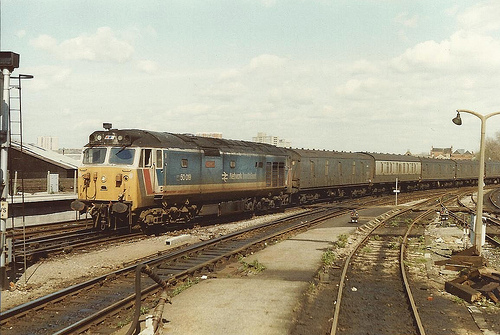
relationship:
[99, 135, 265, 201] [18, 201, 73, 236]
train on track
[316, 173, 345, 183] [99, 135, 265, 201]
dirt on train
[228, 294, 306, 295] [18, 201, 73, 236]
pavement between track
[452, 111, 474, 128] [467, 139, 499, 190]
light on pole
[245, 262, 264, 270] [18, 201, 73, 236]
grass near track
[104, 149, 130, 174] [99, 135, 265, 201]
window on train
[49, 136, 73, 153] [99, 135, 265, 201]
building behind train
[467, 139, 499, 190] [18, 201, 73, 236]
pole near track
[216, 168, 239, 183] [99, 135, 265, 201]
name on train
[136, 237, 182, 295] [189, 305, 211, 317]
wood on ground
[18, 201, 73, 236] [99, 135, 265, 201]
track of train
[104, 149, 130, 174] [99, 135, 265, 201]
window of train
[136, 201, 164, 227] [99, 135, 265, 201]
wheel on train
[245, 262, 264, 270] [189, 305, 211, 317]
grass on ground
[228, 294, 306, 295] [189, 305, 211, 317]
pavement on ground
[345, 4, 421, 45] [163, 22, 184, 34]
clouds in sky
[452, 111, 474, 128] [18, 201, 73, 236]
light next to track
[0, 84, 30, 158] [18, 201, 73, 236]
ladder next to track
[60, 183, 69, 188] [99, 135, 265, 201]
fence behind train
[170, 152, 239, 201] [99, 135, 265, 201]
door of train